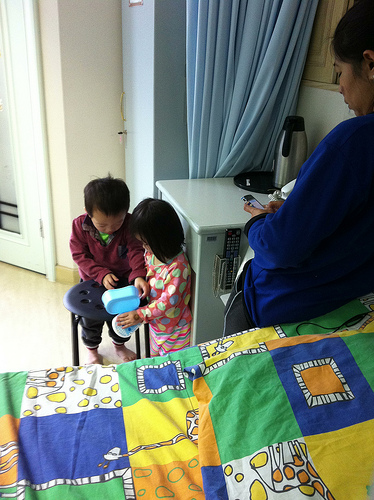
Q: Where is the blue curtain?
A: Behind Grey box.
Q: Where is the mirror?
A: On door.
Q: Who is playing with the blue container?
A: 2 children.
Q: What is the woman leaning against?
A: A bed.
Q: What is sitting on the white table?
A: A carafe.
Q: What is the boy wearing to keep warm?
A: A purple jacket.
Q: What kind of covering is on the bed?
A: A quilt.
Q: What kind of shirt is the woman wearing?
A: A blue long sleeved top.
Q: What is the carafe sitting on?
A: A black tray.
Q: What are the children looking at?
A: A blue container.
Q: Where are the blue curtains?
A: Pushed back by the wall?.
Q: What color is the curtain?
A: Blue.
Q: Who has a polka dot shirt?
A: The little girl.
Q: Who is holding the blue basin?
A: The little boy.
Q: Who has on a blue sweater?
A: The woman.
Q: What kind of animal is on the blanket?
A: Giraffes.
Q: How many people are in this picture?
A: Three.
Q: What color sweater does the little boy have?
A: Red.